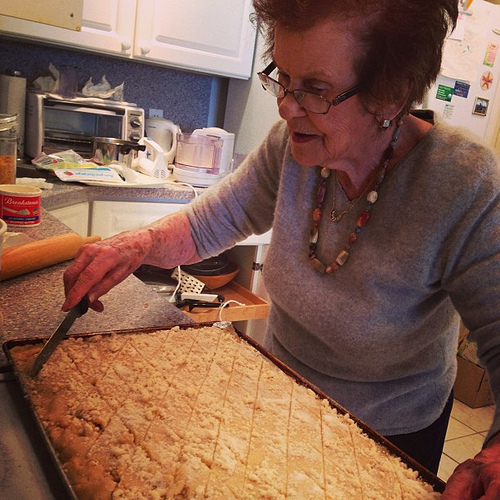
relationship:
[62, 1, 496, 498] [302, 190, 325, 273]
woman wearing necklace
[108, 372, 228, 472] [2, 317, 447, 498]
dessert on tray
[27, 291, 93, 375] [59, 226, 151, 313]
knife in hand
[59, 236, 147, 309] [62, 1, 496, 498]
hand of woman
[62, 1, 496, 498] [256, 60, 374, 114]
woman wearing eyeglasses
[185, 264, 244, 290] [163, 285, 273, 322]
bowl on shelf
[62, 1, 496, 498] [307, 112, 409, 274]
woman wearing necklace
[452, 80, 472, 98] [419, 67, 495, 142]
magnet on refrigerator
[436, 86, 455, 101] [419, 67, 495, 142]
magnet on refrigerator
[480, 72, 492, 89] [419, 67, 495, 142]
magnet on refrigerator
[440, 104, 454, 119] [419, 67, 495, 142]
magnet on refrigerator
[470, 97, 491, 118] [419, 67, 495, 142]
magnet on refrigerator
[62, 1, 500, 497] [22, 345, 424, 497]
woman cutting pastry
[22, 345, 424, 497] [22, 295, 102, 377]
pastry with knife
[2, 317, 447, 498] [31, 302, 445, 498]
tray of pastries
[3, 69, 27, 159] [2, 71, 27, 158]
roll of paper towels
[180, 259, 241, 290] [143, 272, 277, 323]
bowl on a pullout drawer